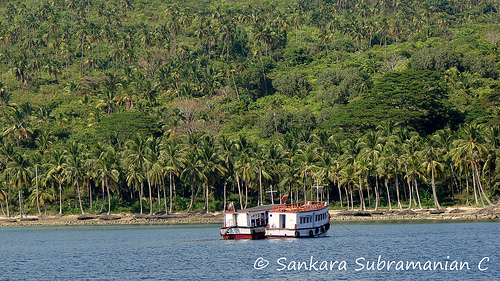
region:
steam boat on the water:
[214, 178, 333, 230]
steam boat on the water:
[271, 193, 338, 239]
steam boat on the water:
[208, 185, 272, 244]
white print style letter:
[276, 248, 286, 273]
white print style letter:
[286, 259, 298, 274]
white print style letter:
[296, 258, 309, 273]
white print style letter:
[308, 255, 320, 273]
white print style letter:
[318, 260, 327, 270]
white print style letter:
[327, 259, 337, 275]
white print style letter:
[337, 258, 347, 272]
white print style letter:
[354, 253, 366, 274]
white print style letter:
[364, 258, 374, 271]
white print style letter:
[375, 254, 385, 274]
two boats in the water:
[219, 192, 335, 245]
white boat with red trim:
[265, 200, 337, 238]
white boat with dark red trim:
[213, 197, 271, 239]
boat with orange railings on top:
[265, 196, 330, 243]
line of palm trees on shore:
[0, 141, 499, 208]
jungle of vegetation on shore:
[1, 3, 498, 207]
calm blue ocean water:
[1, 222, 491, 276]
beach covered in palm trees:
[3, 137, 499, 218]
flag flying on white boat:
[223, 196, 238, 216]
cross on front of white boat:
[311, 179, 324, 202]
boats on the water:
[206, 188, 338, 244]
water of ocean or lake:
[4, 218, 495, 277]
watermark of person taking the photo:
[245, 245, 496, 277]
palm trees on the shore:
[7, 128, 493, 208]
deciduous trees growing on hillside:
[329, 58, 459, 135]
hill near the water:
[5, 5, 496, 188]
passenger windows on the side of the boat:
[291, 208, 334, 229]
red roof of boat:
[269, 194, 329, 215]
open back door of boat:
[272, 210, 292, 233]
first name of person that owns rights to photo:
[273, 255, 348, 277]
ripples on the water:
[12, 230, 454, 278]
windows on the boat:
[293, 207, 336, 228]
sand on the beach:
[0, 205, 494, 233]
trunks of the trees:
[2, 173, 484, 228]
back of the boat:
[260, 208, 298, 240]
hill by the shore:
[3, 22, 491, 149]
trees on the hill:
[8, 6, 490, 163]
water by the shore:
[2, 216, 494, 270]